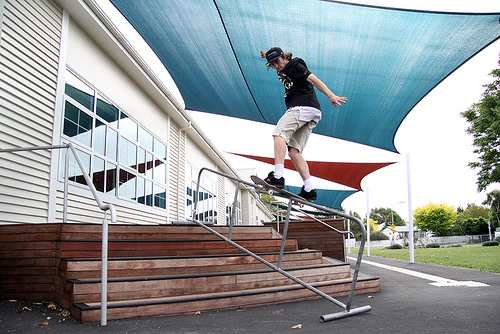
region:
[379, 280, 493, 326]
paved ground for walking on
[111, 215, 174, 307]
staircase for walking up/down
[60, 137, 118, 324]
hand rails to use for assistance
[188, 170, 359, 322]
rail specifically designed for skateboarders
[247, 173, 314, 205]
skateboard being used to grind on rail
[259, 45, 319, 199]
male standing on board on rail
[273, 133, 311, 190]
leg muscles for strength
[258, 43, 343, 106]
arms out for balance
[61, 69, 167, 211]
window for seeing through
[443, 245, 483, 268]
grass for napping on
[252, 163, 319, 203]
skateboard with white wheels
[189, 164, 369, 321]
a portable railing down stairs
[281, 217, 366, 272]
supporting wall for raised walkway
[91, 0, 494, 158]
a blue overhead tarp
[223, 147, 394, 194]
a red triangle tarp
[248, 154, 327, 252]
skateboard on a metal railing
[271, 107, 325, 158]
man's knee length shorts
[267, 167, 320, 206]
black sneakers with white socks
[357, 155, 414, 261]
white poles along the grass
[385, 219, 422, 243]
white house in the distance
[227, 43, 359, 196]
the man is skateboarding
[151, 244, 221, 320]
the steps are brown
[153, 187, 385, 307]
the rail is going downward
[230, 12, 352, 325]
the man is skateboarding on a rail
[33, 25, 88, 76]
the wall is a shade of white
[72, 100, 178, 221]
the window seals are white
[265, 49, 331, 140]
the mans shirt is black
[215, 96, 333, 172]
the mans shorts are an off white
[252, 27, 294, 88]
the mans hat is black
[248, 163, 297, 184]
the mans socks are white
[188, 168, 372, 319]
Railing is made of steel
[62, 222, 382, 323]
steps are made of wood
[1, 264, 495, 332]
ground is black top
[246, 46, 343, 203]
man wearing black shoes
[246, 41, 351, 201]
man wearing white socks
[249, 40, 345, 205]
man wearing tan pants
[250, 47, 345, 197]
man wearing black shirt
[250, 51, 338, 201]
man wearing black hat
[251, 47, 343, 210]
man riding on skateboard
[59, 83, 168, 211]
windows made of glass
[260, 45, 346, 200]
a man on a skateboard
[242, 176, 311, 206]
the skateboard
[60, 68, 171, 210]
a window on the building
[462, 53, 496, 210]
a tree in the grass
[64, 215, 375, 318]
wooden stairs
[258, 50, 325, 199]
a man in a black shirt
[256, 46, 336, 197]
a man in a black cap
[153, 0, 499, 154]
a blue canopy hung up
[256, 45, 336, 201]
a man wearing khaki shorts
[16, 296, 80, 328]
leaves on the ground